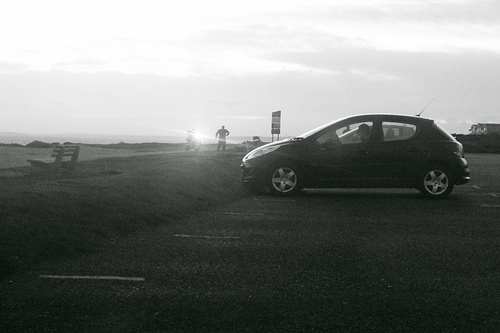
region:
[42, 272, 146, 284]
The short white stripe on the ground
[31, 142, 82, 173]
The bench in the corner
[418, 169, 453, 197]
The wheel on the car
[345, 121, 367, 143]
Person sitting in their car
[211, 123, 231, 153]
A man standing on the beach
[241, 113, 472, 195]
A parked car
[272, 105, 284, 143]
A sign on the beach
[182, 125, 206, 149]
The setting sun glare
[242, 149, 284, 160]
The head light on the car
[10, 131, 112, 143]
The mountains in the distance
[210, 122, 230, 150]
a man standing in front of the sun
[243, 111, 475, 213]
a car parked at the beach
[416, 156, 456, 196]
the rear wheel of a car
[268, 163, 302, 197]
the front wheel of a car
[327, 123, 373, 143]
the driver's side window of a car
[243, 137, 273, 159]
the headlight of a car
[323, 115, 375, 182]
the driver's side door of a car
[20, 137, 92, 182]
a bench at the seashore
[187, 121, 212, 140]
the sun setting on the water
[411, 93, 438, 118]
the antennae of a car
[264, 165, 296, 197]
tire on the car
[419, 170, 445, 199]
tire on the car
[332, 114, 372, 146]
window on the car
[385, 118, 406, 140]
window on the car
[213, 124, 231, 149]
person on the road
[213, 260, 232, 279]
patch of black asphalt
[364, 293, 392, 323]
patch of black asphalt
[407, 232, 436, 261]
patch of black asphalt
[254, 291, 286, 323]
patch of black asphalt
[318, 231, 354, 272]
patch of black asphalt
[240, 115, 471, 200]
A small black car.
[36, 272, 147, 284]
A white line on the road.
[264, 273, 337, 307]
Part of the road.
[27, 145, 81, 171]
An empty bench.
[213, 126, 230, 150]
A person walking.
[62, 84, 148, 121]
Part of the sky.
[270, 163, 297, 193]
The front tire on the car.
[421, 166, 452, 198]
The back tire on the car.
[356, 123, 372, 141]
A person sitting in the car.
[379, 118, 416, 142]
The rear car window.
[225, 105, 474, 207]
a hatchback car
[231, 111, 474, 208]
a small car with four doors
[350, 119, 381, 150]
someone sitting in their vehicle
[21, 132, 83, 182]
a bench in grass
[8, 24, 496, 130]
very cloudy sky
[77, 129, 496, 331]
a parking lot with faded paint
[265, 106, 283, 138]
a metal sign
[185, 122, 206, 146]
the sun shining brightly near the horizon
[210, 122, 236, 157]
a person out walking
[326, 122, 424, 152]
a car seen through the windows of another car